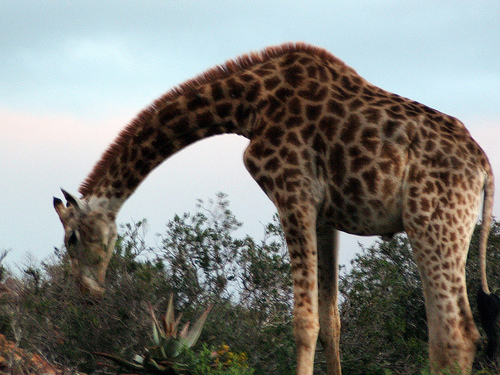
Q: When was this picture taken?
A: Daytime.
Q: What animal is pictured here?
A: A giraffe.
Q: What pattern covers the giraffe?
A: Spots.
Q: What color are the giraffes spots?
A: Brown.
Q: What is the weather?
A: Sunny.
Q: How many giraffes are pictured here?
A: 1.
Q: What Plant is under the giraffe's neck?
A: Aloe.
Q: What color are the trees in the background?
A: Green.